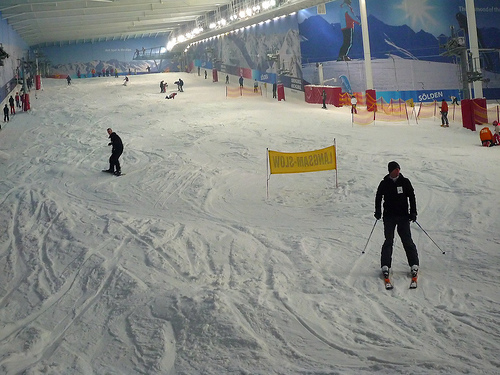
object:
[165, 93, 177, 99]
people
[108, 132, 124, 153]
jacket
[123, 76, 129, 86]
people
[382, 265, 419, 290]
skis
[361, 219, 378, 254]
pole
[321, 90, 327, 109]
barrier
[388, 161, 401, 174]
beanie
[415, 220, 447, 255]
pole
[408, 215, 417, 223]
hand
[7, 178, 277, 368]
trail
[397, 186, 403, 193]
square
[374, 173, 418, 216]
coat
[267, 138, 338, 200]
banner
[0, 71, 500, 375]
slope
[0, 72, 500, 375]
hill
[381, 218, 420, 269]
pants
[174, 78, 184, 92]
people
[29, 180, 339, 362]
snow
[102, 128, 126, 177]
he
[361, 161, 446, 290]
he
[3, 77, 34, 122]
people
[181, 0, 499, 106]
wall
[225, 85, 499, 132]
fence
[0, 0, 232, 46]
ceiling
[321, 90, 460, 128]
picture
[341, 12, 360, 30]
shirt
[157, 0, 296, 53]
lights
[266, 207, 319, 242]
white